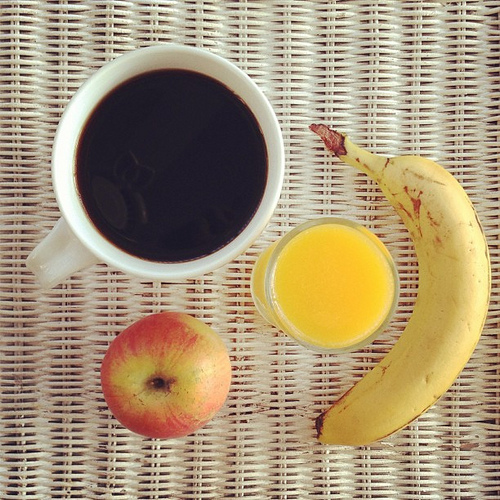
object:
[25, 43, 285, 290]
coffee cup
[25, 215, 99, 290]
handle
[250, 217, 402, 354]
glass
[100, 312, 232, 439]
apple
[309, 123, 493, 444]
banana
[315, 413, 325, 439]
spot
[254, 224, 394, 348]
juice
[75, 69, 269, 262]
coffee